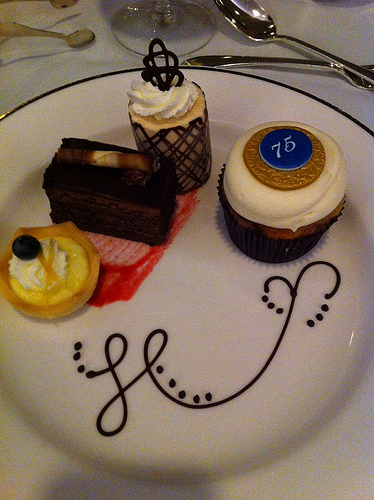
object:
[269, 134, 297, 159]
number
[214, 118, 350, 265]
cupcake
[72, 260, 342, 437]
design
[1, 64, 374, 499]
plate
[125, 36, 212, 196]
pastry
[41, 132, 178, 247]
cake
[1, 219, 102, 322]
tart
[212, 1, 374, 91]
spoon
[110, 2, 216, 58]
base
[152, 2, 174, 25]
stem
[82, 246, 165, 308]
syrup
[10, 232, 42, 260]
blueberry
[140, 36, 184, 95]
florish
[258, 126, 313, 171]
circle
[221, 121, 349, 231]
frosting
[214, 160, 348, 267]
wrapper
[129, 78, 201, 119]
whip cream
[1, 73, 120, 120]
trim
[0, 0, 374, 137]
tablecloth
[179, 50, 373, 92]
fork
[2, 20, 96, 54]
spoon